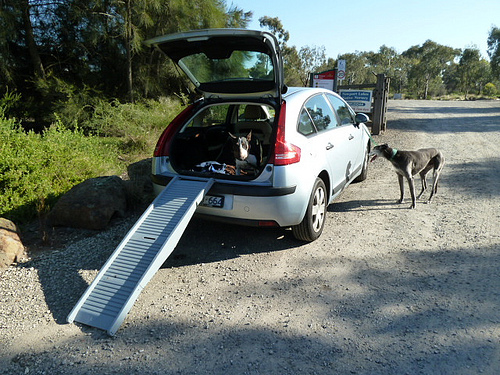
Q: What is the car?
A: Hatchback.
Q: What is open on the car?
A: Hatch.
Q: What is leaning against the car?
A: Ramp.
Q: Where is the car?
A: On the road.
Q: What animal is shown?
A: A dog.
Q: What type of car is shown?
A: White.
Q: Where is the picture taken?
A: The road.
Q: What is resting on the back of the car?
A: A ramp.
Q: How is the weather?
A: Sunny.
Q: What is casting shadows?
A: Trees.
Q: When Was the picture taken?
A: Afternoon.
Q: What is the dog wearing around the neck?
A: A collar.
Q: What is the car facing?
A: A gate.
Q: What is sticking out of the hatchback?
A: Ramp.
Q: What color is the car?
A: Silver.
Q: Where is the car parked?
A: On dirt.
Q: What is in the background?
A: Trees.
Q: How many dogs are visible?
A: 2.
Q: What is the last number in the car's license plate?
A: 4.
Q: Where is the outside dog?
A: Near the door.